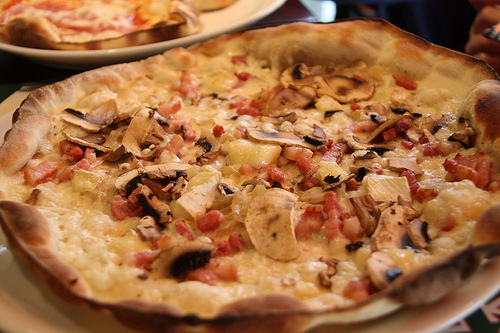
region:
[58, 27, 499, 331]
Pizza is seen.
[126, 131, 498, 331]
Pizza is on plate.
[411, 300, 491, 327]
plate is white color.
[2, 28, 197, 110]
Two plates are seen.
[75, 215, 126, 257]
Cheese is white color.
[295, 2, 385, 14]
table is black color.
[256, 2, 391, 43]
Plates are in the table.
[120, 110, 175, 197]
Mushrooms are brown color.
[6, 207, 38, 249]
Bread is brown color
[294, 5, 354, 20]
light reflection in table.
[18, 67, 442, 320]
this is a pizza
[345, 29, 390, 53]
the pizza is brown in color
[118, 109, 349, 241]
these are some spices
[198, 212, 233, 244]
the spices are red in color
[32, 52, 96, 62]
this is a plate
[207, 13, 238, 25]
the plate is white in color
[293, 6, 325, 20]
this is a table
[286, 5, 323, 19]
the table is wooden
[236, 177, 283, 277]
some spices are yellow in color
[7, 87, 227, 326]
the pizza is on the plate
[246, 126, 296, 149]
A mushroom which is a vegetable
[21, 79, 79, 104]
a crisp crust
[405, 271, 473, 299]
a portion of the crust is burned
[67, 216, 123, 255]
This food item has cheese on it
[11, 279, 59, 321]
This food item is sitting on a white plate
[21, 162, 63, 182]
This pizza has tomatoes on it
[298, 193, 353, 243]
There are a lot of tomatoes on this pizza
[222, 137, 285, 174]
This is a piece of pineapple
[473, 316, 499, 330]
The table is colorful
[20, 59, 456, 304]
This is a handmade pizza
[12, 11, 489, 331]
A cooked pizza is in the foreground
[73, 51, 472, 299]
Pizza has a topping of mushrooms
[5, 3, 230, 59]
another pizza is in the background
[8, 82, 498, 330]
Pizza is on a plate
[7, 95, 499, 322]
The plate is white in color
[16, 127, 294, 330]
The pizza crust is thin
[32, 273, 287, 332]
Edge of the crust is burned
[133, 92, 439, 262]
The pizza has chopped meat toppings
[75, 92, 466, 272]
The mushroom toppings are chopped up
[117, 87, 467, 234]
The cheese is a light tan color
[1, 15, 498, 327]
pizza full of various toppings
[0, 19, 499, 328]
brown crispy crust of pizza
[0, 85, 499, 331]
white plate under pizza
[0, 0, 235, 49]
another pizza behind other pizza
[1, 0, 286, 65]
white plate behind pizza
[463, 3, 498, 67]
hand to right of pizza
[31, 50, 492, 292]
white cheese on top of pizza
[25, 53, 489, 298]
pink topping dot top of pizza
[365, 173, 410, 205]
white chink of chicken on pizza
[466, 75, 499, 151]
bubble in side of crust